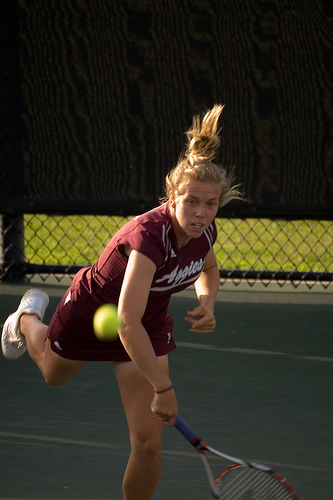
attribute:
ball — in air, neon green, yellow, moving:
[91, 303, 127, 339]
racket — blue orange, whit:
[173, 413, 300, 498]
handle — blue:
[173, 417, 209, 453]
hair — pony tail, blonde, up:
[156, 101, 251, 211]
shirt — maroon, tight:
[78, 199, 220, 311]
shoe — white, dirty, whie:
[2, 289, 53, 362]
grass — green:
[24, 214, 331, 273]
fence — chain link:
[1, 205, 332, 293]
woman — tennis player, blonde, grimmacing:
[2, 100, 251, 499]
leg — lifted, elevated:
[1, 271, 91, 388]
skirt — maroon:
[45, 267, 181, 361]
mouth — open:
[188, 221, 209, 229]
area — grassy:
[14, 193, 332, 275]